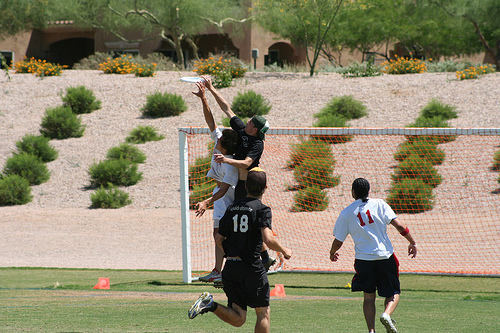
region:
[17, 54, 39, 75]
bush with yellow flowers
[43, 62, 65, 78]
bush with yellow flowers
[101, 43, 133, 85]
bush with yellow flowers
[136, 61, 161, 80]
bush with yellow flowers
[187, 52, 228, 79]
bush with yellow flowers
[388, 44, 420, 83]
bush with yellow flowers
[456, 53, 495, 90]
bush with yellow flowers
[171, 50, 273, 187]
two men jumping up to catch a Frisbee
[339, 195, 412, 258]
man wearing white shirt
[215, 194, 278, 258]
man wearing black shirt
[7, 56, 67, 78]
the flower bush on the ground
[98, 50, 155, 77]
the flower bush on the ground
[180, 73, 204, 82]
the frisbee in the air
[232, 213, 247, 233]
the number 18 on the shirt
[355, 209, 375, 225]
the number 11 on the shirt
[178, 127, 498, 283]
the net on the field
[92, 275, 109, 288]
the orange cone on the ground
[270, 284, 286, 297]
the orange cone on the ground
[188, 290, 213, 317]
the shoe on the man's foot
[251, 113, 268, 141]
the hat on the man's head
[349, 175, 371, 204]
The man has black hair.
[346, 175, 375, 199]
The man's hair is in cornrows.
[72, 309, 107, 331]
The grass is green.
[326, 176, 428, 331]
The man is on a soccer field.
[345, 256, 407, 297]
The man is wearing black shorts.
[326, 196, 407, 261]
The man is wearing a white shirt.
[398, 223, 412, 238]
The man is wearing a red arm band.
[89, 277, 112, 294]
The cone is orange.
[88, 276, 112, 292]
The cone is on the soccer field.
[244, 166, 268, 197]
The man's hair is short.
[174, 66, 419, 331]
group of people playing Frisbee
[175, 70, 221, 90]
white Frisbee in the air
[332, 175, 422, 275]
person wearing white shirt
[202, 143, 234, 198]
person wearing white shirt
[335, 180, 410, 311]
man wearing black shorts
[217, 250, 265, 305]
man wearing black shorts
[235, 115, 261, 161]
man wearing black shirt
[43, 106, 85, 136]
green bush on hill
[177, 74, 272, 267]
two guys reaching for a frisbee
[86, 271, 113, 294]
an orange cone on the ground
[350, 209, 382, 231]
red numbers on a shirt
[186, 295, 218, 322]
a gray and white sneaker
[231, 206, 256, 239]
a white number on a black jersey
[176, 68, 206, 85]
a white frisbee in the air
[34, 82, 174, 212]
rows of small green shrubs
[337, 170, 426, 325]
a man with a ponytail and blacks shorts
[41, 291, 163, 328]
green grass on the ground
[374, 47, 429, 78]
a bush of yellow flowers